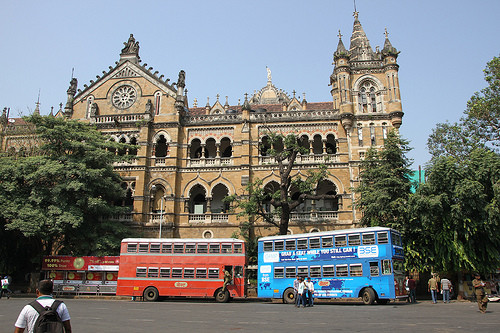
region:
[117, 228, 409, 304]
Two buses parked by the trees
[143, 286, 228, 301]
Wheels on the bus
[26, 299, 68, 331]
The man is wearing a backpack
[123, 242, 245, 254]
Windows on the bus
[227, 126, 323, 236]
A tree next to the building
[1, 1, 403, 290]
A building surrounded by trees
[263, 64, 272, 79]
A statue on top of the building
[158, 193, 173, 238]
A lamp post next to the bus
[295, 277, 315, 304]
People standing near the bus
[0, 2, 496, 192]
The sky above the building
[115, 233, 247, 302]
red double decker bus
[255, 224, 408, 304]
blue double decker bus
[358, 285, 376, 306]
black tire on the blue bus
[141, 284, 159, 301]
black tire on the red bus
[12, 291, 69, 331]
white shirt on the man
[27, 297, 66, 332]
black backpack on the man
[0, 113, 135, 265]
large green tree in front of the building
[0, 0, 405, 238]
building behind the busses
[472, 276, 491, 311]
person wearing all brown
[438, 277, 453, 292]
gray shirt on the person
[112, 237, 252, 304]
a red double decked bus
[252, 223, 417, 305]
a blue double decked bus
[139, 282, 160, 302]
the wheel of a bus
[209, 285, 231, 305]
the wheel of a bus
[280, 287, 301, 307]
the wheel of a bus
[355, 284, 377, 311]
the wheel of a bus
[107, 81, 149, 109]
a round window of a building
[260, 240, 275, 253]
a window of a bus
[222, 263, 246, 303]
the door of a bus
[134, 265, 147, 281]
a window of a bus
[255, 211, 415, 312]
a tall blue two story bus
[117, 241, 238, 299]
a tall red two story bus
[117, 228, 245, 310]
the side of a red bus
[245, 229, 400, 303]
the side of a blue bus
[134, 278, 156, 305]
the back wheel of a bus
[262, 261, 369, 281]
the windows of the first story of a bus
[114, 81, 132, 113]
a clock on a big church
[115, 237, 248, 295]
a red bus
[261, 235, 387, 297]
a blue bus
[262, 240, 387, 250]
windows on the blue bus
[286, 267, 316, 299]
people standing in front of the bus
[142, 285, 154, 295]
the tire of the bus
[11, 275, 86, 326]
a man with a backpack on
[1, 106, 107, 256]
a tree in front of the building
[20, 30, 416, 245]
a large building behind the bus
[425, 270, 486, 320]
people walking in front of the bus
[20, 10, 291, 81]
the sky above the building